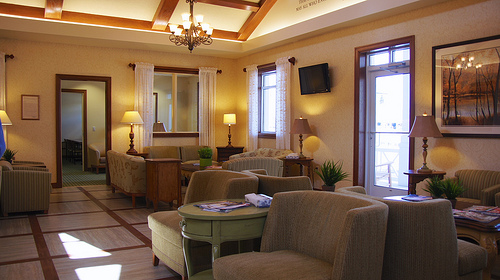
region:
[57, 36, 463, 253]
neat and clean light colored waiting room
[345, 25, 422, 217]
glass door entrance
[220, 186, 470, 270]
tan circular padded chairs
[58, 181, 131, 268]
tan checker pattern on floor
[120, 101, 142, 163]
small lamp on table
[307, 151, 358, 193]
green plant on table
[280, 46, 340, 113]
flat screen television is not turned on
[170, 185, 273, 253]
round table with magazines and tissues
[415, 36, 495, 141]
painting with light reflecting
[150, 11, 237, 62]
ceiling light is on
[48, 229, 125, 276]
this is the floor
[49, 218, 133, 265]
the floor is made of tiles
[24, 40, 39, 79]
this is the wall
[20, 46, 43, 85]
the wall is white in color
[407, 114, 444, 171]
this is a lampshade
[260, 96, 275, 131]
this is a window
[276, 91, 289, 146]
this is a curtain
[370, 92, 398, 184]
this is a door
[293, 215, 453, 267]
these are two couches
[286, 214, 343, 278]
the couch is grey in color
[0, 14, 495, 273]
Large room with no people.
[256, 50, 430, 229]
Two windows looking outside.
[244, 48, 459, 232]
Photo taken during the day.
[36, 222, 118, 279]
Sunlight on the floor.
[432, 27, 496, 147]
Painting on the wall.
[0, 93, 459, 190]
Five lamps in this room.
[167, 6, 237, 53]
Chandelier hanging from the ceiling.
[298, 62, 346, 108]
TV hanging on the wall.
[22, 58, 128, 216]
Doorway to the next room.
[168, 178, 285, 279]
Small table separating chairs.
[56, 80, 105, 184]
this is a door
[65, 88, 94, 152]
thew door is opened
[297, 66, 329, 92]
this is a television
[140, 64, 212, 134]
this is a window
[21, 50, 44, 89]
this is a wall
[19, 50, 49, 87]
the wall is cream in color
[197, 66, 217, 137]
this is a curtain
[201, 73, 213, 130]
the curtain is white in color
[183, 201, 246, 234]
this is a table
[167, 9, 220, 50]
decorative lights hanging from ceiling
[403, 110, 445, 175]
lamp on end table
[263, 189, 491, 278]
two chairs back to back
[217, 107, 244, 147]
lamp in corner of room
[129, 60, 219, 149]
white curtains on wall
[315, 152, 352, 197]
green plant on floor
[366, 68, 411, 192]
door made of glass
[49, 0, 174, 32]
wood beams on ceiling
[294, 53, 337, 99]
flat screen television on wall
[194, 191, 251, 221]
magazines on green table